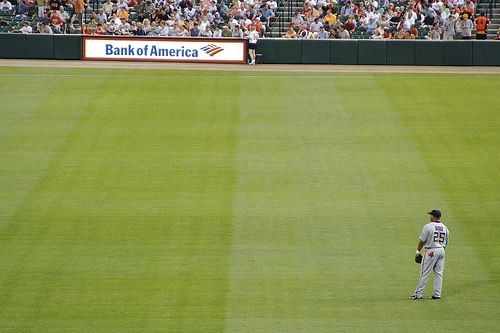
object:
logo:
[198, 42, 223, 56]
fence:
[0, 34, 497, 65]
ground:
[438, 149, 461, 179]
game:
[0, 69, 499, 331]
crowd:
[232, 0, 486, 50]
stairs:
[262, 0, 305, 38]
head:
[425, 208, 444, 223]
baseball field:
[0, 65, 499, 329]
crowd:
[5, 1, 494, 40]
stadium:
[2, 1, 499, 61]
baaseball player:
[409, 207, 448, 299]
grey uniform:
[416, 221, 451, 296]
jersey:
[421, 220, 451, 252]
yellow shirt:
[322, 12, 337, 24]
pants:
[417, 249, 444, 299]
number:
[431, 230, 446, 245]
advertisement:
[77, 37, 244, 64]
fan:
[473, 10, 490, 37]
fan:
[456, 12, 474, 38]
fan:
[278, 24, 299, 37]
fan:
[301, 25, 318, 35]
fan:
[316, 24, 331, 38]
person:
[244, 22, 263, 68]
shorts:
[246, 41, 258, 51]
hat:
[427, 207, 444, 216]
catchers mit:
[411, 250, 429, 263]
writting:
[434, 224, 447, 245]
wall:
[4, 28, 500, 69]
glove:
[412, 251, 424, 265]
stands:
[5, 1, 479, 40]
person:
[321, 6, 337, 26]